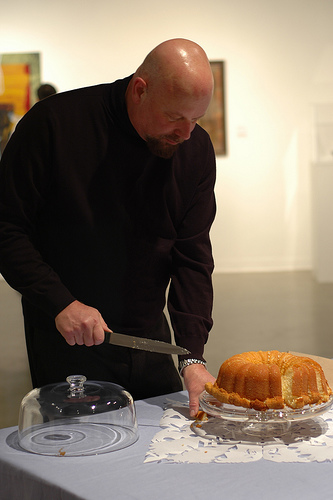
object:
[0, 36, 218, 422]
man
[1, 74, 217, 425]
clothes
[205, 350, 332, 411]
cake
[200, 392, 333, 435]
cake stand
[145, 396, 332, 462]
doily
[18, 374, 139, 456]
cover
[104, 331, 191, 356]
knife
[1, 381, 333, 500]
table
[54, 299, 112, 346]
hand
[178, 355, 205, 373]
wrist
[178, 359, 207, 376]
watch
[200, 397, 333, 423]
edge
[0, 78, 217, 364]
shirt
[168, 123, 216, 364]
sleeve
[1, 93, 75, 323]
sleeve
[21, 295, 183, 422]
pants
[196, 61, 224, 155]
picture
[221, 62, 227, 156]
edge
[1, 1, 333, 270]
wall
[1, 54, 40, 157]
picture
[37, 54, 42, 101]
edge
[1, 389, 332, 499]
table cloth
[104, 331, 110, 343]
handle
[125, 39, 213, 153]
head